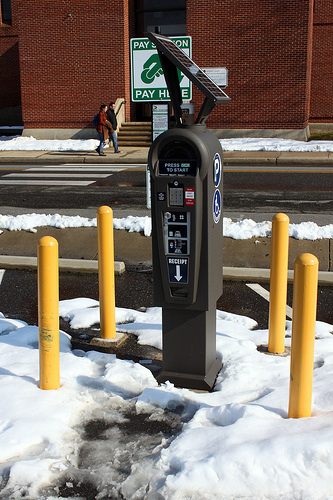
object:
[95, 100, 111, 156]
woman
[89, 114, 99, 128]
backpack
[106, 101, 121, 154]
man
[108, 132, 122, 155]
jeans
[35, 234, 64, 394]
pole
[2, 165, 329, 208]
street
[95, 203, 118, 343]
pole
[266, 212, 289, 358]
pole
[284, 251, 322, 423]
pole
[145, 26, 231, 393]
parking meter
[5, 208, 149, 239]
snow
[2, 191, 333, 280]
sidewalk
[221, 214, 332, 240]
snow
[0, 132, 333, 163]
sidewalk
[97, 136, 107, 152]
jeans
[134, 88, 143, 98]
letter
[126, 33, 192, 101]
sign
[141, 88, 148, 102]
letter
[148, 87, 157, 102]
letter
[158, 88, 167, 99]
letter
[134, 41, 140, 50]
letter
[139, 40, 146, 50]
letter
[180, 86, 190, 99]
letter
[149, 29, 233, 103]
solar panel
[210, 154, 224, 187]
sign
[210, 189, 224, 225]
sign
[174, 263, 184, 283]
arrow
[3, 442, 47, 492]
footprint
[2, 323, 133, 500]
snow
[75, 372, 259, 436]
shadow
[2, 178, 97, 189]
line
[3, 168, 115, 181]
line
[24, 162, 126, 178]
line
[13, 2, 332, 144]
building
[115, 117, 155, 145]
stairs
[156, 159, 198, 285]
instructions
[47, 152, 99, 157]
shadow